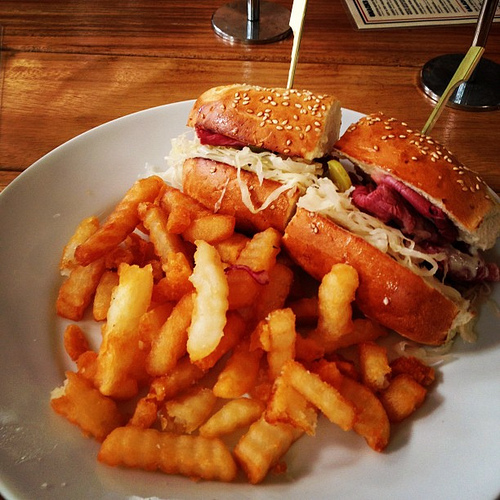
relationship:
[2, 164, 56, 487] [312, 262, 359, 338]
white plate holding food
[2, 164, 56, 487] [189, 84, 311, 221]
white plate holding food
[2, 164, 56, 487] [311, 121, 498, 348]
white plate holding food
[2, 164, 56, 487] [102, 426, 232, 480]
white plate holding food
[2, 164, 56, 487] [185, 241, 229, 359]
white plate holding food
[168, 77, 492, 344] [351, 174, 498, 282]
reuben sandwich filled with beef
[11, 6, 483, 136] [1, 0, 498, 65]
grain in board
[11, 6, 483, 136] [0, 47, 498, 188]
grain in board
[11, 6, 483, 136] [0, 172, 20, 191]
grain in board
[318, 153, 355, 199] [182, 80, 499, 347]
pickle in sandwich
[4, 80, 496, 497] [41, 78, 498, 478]
plate with sandwich/fries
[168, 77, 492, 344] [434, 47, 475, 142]
reuben sandwich with toothpick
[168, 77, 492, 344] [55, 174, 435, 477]
reuben sandwich with french fries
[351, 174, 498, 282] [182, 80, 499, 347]
beef on sandwich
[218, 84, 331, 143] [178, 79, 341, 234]
seeds on top of bun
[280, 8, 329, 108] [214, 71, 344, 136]
toothpick poked into bun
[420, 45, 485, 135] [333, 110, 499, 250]
toothpick in bun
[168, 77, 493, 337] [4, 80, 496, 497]
reuben sandwich on plate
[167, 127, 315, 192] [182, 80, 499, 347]
sauerkraut in sandwich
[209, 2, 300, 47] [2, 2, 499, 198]
silver base on table